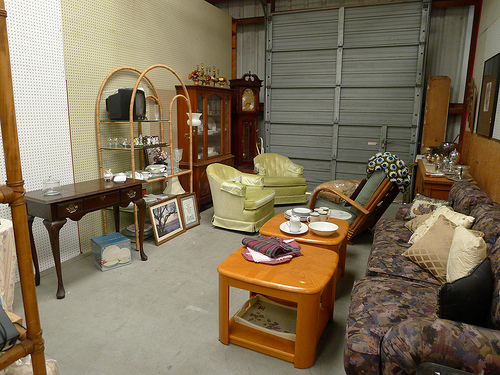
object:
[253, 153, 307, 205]
chair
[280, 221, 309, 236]
white dish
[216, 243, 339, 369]
table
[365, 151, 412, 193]
afghan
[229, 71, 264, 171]
clock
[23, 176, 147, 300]
desk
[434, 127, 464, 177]
ground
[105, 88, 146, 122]
tv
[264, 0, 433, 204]
garage door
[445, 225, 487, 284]
pillow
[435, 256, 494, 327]
pillow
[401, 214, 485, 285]
pillow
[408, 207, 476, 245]
pillow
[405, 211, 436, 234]
pillow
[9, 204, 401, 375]
ground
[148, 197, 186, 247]
pictures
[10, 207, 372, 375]
floor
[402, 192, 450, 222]
pillows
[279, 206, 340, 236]
dishes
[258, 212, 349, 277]
table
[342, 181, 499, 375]
couch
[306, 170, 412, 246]
chair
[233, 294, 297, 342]
tray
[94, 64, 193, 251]
shelf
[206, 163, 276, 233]
chair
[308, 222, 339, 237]
bowl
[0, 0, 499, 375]
room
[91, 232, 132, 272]
box